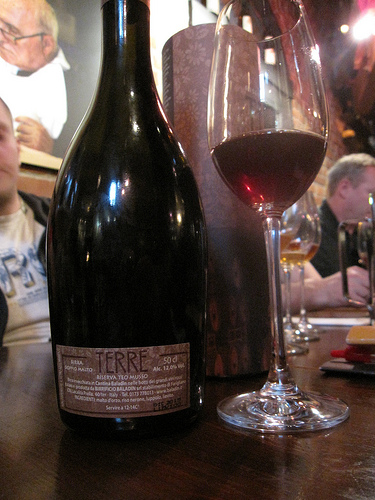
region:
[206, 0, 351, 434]
wine in a glass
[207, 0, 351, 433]
a long stem glass containing red wine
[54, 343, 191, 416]
the label on the bottom side of wine bottle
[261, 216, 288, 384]
tall stem on the glass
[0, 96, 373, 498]
three people drinking wine at the table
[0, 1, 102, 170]
portrait of a man on the wall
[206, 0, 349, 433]
four wine stem glasses on the table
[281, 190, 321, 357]
three glasses of white wine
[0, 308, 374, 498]
a dark brown table in a restaurant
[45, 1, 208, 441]
a wine bottle on the table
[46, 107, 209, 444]
dark bottle of alcohol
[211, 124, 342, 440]
glass of red wine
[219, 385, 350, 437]
base of wine glass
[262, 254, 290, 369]
stem of wine glass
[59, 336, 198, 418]
label on wine bottle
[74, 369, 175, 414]
white words on label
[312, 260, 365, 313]
human hand on table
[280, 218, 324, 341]
row of three glasses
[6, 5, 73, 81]
picture of man on wall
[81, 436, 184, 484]
shadow on wood table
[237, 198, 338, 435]
The stem of a wine glass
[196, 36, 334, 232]
A glass of red wine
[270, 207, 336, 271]
Glasses of white wine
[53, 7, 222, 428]
A bottle of wine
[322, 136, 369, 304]
A man sitting at the table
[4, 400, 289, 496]
A wooden dinner table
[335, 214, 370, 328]
The metal arm of the stein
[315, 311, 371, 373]
A stack of coasters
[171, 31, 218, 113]
A floral print on a wrap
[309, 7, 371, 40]
Bright lights in the bar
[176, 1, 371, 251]
the glass is clear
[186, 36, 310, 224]
the glass is clear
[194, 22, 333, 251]
the glass has wine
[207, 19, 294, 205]
the glass has wine